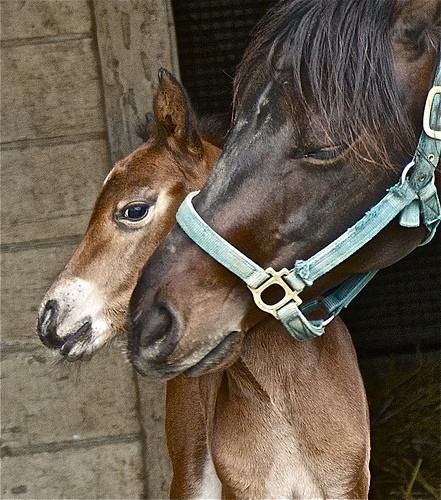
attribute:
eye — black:
[119, 202, 153, 227]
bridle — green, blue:
[173, 57, 438, 340]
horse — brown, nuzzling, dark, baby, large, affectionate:
[126, 3, 437, 383]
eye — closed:
[292, 133, 362, 172]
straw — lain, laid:
[367, 351, 441, 498]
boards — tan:
[2, 1, 156, 495]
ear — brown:
[153, 70, 207, 164]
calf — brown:
[36, 61, 375, 499]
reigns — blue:
[177, 59, 440, 344]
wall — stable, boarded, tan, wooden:
[1, 1, 206, 500]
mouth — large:
[132, 329, 243, 382]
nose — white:
[30, 302, 61, 341]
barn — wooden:
[4, 0, 438, 500]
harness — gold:
[252, 268, 299, 319]